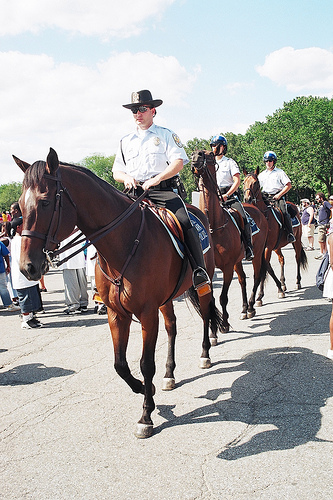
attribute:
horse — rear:
[241, 171, 314, 300]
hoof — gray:
[133, 420, 156, 439]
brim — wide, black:
[146, 98, 163, 106]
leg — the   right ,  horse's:
[135, 306, 159, 438]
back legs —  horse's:
[153, 286, 212, 393]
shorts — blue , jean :
[13, 285, 43, 314]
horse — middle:
[181, 139, 281, 356]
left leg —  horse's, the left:
[135, 307, 159, 438]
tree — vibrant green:
[255, 95, 331, 192]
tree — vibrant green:
[245, 121, 266, 165]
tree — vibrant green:
[179, 130, 237, 187]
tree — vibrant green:
[78, 154, 126, 186]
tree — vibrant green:
[1, 183, 22, 205]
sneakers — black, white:
[18, 314, 44, 328]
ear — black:
[43, 147, 63, 176]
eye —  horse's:
[34, 197, 49, 206]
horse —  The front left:
[7, 135, 259, 392]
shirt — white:
[88, 109, 224, 191]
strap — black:
[96, 198, 185, 321]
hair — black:
[21, 159, 48, 187]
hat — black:
[122, 90, 163, 110]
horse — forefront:
[10, 139, 230, 440]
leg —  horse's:
[105, 304, 155, 395]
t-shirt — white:
[9, 231, 40, 289]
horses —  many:
[1, 144, 309, 443]